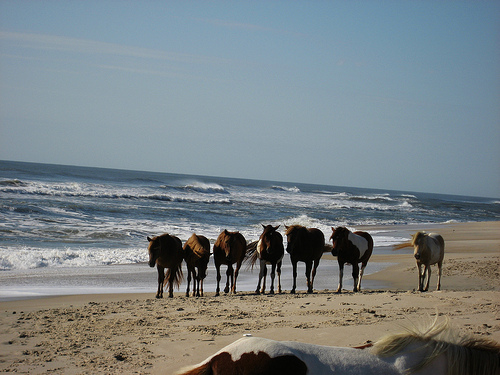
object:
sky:
[0, 0, 500, 198]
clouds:
[194, 42, 205, 53]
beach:
[0, 288, 500, 375]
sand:
[7, 286, 500, 375]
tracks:
[109, 332, 126, 344]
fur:
[226, 232, 251, 254]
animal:
[144, 221, 447, 300]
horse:
[392, 228, 446, 291]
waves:
[59, 188, 79, 192]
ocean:
[0, 157, 500, 296]